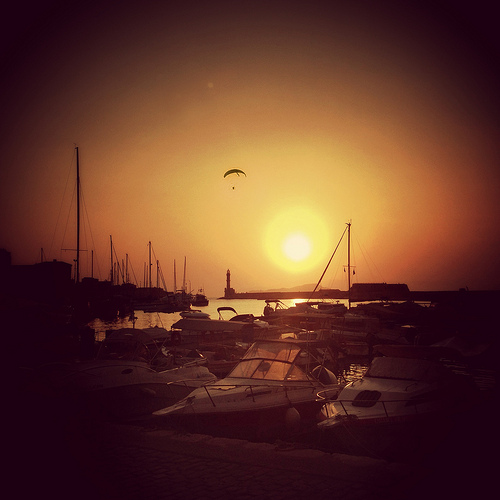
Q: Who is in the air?
A: Parachuter.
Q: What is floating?
A: Boat.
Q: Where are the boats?
A: In water.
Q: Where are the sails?
A: On boats.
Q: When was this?
A: During the day.